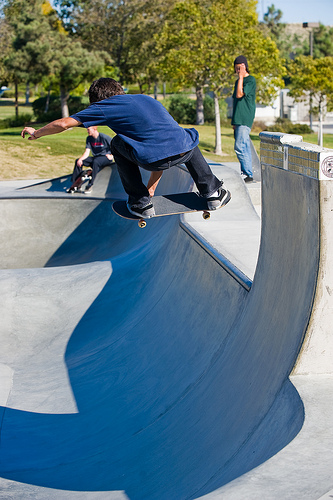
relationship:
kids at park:
[55, 80, 292, 213] [38, 82, 331, 380]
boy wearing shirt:
[228, 52, 260, 185] [230, 69, 257, 130]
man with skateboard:
[73, 126, 116, 195] [64, 158, 90, 193]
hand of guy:
[145, 184, 155, 197] [4, 68, 236, 230]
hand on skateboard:
[145, 184, 155, 197] [109, 192, 232, 227]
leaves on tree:
[157, 30, 259, 72] [146, 0, 287, 154]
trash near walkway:
[279, 102, 313, 129] [2, 151, 266, 244]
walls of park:
[93, 126, 329, 499] [1, 3, 92, 44]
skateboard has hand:
[64, 158, 90, 193] [17, 121, 52, 145]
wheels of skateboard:
[134, 210, 212, 227] [105, 186, 232, 230]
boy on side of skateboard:
[13, 71, 234, 220] [110, 185, 231, 228]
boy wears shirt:
[229, 52, 257, 185] [229, 72, 255, 124]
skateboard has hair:
[64, 158, 90, 193] [85, 75, 128, 101]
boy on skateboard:
[13, 71, 234, 220] [100, 168, 249, 232]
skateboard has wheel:
[109, 181, 235, 228] [134, 219, 148, 229]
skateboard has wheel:
[109, 181, 235, 228] [200, 208, 213, 221]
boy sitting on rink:
[63, 123, 114, 196] [0, 153, 250, 291]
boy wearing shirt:
[13, 71, 234, 220] [67, 90, 202, 163]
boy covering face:
[228, 52, 260, 185] [235, 59, 248, 72]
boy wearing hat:
[228, 52, 260, 185] [224, 51, 265, 71]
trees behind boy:
[0, 4, 332, 120] [13, 71, 234, 220]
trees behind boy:
[0, 4, 332, 120] [222, 50, 268, 183]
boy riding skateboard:
[13, 71, 234, 220] [92, 187, 241, 226]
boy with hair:
[13, 71, 234, 220] [86, 73, 126, 104]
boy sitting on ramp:
[63, 123, 114, 196] [0, 131, 333, 496]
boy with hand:
[228, 52, 260, 185] [234, 61, 248, 75]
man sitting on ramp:
[73, 126, 116, 195] [0, 131, 333, 496]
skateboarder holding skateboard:
[21, 73, 233, 220] [110, 185, 231, 228]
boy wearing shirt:
[228, 52, 260, 185] [233, 75, 257, 129]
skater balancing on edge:
[108, 188, 234, 225] [175, 164, 251, 291]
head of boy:
[232, 53, 251, 76] [216, 50, 274, 184]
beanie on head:
[234, 55, 247, 62] [232, 53, 251, 76]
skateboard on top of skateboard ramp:
[121, 181, 257, 226] [4, 131, 332, 496]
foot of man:
[71, 168, 85, 180] [73, 126, 116, 195]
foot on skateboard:
[71, 168, 85, 180] [64, 169, 93, 192]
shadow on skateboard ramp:
[2, 202, 252, 498] [4, 131, 332, 496]